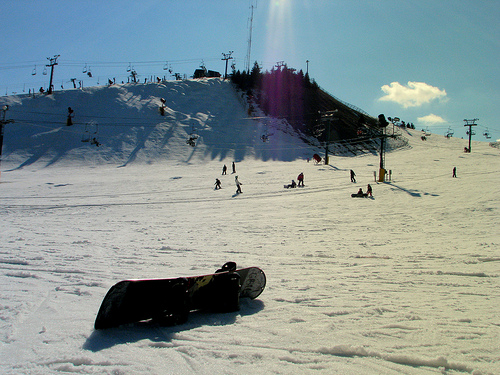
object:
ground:
[0, 129, 500, 375]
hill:
[0, 71, 500, 171]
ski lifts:
[31, 67, 38, 76]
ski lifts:
[356, 126, 376, 141]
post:
[378, 168, 385, 182]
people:
[233, 175, 243, 196]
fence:
[334, 142, 381, 156]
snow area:
[0, 194, 500, 375]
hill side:
[0, 72, 380, 171]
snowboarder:
[186, 134, 199, 147]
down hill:
[0, 78, 328, 167]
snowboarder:
[261, 134, 267, 143]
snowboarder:
[159, 101, 168, 116]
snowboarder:
[67, 106, 77, 127]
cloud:
[374, 78, 450, 110]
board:
[92, 259, 267, 330]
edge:
[251, 266, 268, 300]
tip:
[94, 281, 121, 329]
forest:
[231, 58, 320, 129]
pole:
[381, 127, 384, 169]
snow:
[0, 121, 215, 235]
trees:
[249, 60, 263, 89]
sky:
[0, 0, 500, 141]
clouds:
[415, 112, 451, 127]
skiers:
[297, 171, 306, 187]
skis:
[232, 191, 244, 198]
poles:
[324, 118, 331, 165]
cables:
[334, 111, 382, 132]